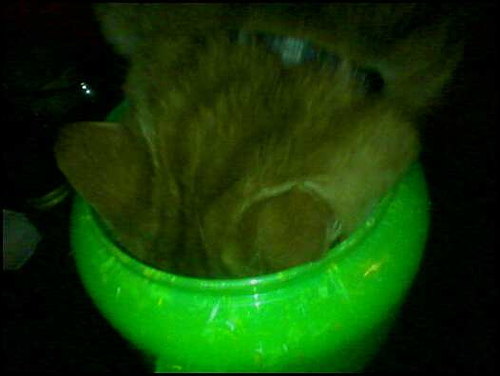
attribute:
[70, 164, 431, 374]
dish — green 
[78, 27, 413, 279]
cat — green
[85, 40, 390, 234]
cat — pictured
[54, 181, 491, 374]
flake — green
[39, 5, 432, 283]
cat — green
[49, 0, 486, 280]
yellow cat — green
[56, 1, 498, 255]
cat — green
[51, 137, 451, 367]
jar — green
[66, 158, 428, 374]
vase — green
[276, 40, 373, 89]
clip — black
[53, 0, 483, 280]
cat — yellow 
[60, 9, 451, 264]
cat — silver 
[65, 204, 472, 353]
bowl — green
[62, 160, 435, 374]
pot — green